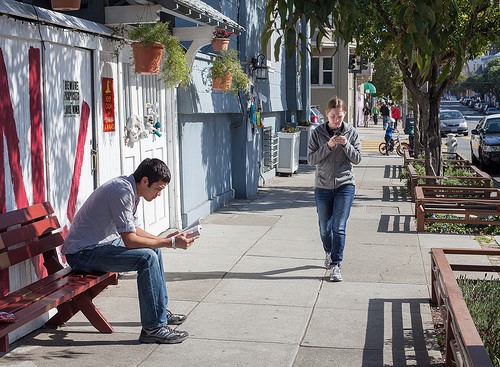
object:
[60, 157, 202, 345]
man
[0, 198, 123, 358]
bench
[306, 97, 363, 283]
woman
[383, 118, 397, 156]
kid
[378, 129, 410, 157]
bike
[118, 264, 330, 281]
shadow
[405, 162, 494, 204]
fence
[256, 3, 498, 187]
tree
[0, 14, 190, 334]
wall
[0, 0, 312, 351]
building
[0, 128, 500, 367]
pavement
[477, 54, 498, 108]
tree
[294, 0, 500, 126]
background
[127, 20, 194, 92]
plants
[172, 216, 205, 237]
book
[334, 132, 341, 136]
phone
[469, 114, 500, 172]
car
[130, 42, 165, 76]
pot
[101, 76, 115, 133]
sign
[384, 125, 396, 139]
shirt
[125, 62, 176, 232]
doors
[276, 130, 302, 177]
pot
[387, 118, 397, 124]
helmet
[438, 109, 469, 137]
car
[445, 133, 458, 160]
hydrant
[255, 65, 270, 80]
light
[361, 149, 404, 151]
lines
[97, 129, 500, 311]
street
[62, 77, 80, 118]
sign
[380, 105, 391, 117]
shirt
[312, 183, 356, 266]
jeans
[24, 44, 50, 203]
stripe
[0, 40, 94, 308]
doors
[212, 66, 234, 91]
pot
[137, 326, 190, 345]
shoe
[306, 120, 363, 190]
shirt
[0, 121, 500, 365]
ground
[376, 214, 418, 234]
shadow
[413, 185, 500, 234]
fence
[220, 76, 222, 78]
leaves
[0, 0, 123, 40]
awning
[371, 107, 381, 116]
shirt